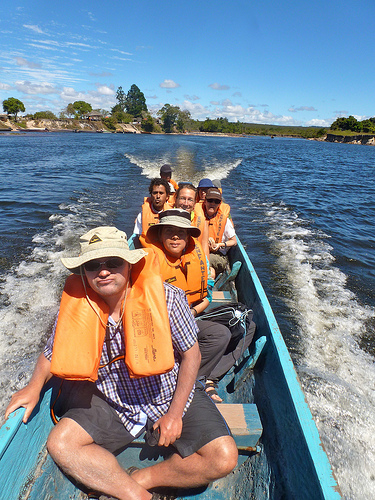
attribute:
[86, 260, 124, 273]
sunglasses — dark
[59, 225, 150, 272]
hat — khaki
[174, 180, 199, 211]
person — smiling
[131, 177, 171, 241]
man — puzzled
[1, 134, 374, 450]
canoe — river, rippling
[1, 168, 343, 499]
boat — turquoise, wooden, blue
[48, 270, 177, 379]
lifevest — orange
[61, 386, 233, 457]
shorts — black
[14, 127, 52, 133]
dock — distant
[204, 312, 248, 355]
bag — black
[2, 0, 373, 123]
sky — blue